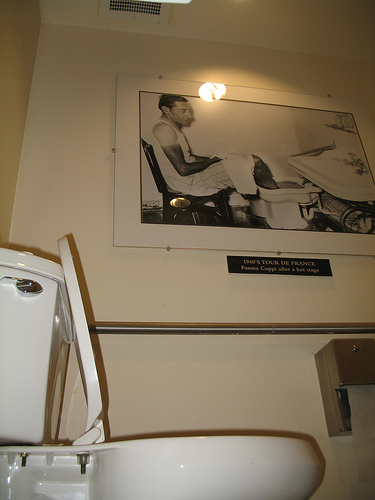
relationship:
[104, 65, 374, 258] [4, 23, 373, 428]
photograph on wall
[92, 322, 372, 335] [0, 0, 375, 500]
railing in public restroom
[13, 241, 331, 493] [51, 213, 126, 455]
toilet with seat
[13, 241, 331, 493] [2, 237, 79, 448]
toilet with tank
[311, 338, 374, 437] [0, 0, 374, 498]
shelf attached to wall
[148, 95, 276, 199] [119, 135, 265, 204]
athlete sitting chair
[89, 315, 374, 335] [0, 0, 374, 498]
metal bar on wall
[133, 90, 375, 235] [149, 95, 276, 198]
photograph of athlete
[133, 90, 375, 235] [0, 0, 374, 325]
photograph hanging in wall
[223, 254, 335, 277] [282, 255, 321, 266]
sign with letters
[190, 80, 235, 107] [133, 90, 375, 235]
light onto photograph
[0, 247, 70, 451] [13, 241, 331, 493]
tank on toilet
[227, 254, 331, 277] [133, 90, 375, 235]
sign under photograph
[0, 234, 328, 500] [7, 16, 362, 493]
toilet in a public restroom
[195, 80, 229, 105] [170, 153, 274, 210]
reflection on glass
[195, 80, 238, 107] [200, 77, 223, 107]
reflection of a light